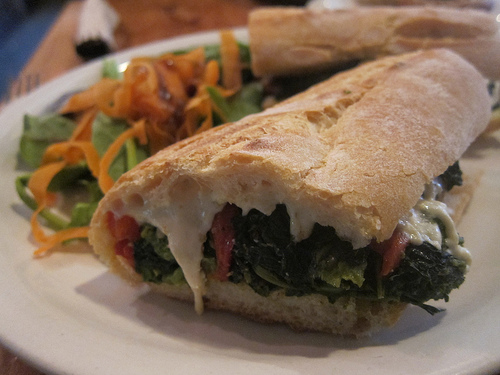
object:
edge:
[0, 347, 117, 373]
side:
[429, 147, 496, 373]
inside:
[21, 253, 292, 353]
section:
[11, 36, 250, 253]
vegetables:
[93, 101, 129, 141]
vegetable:
[208, 86, 260, 116]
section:
[318, 63, 483, 208]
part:
[409, 275, 427, 292]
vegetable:
[395, 246, 470, 308]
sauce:
[119, 178, 447, 307]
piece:
[120, 47, 493, 212]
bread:
[83, 46, 493, 334]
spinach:
[7, 120, 77, 174]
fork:
[7, 69, 43, 100]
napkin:
[75, 8, 129, 54]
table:
[0, 0, 292, 111]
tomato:
[194, 201, 240, 287]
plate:
[0, 26, 500, 373]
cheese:
[69, 46, 251, 155]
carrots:
[116, 52, 226, 160]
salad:
[14, 31, 311, 289]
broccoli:
[226, 216, 422, 300]